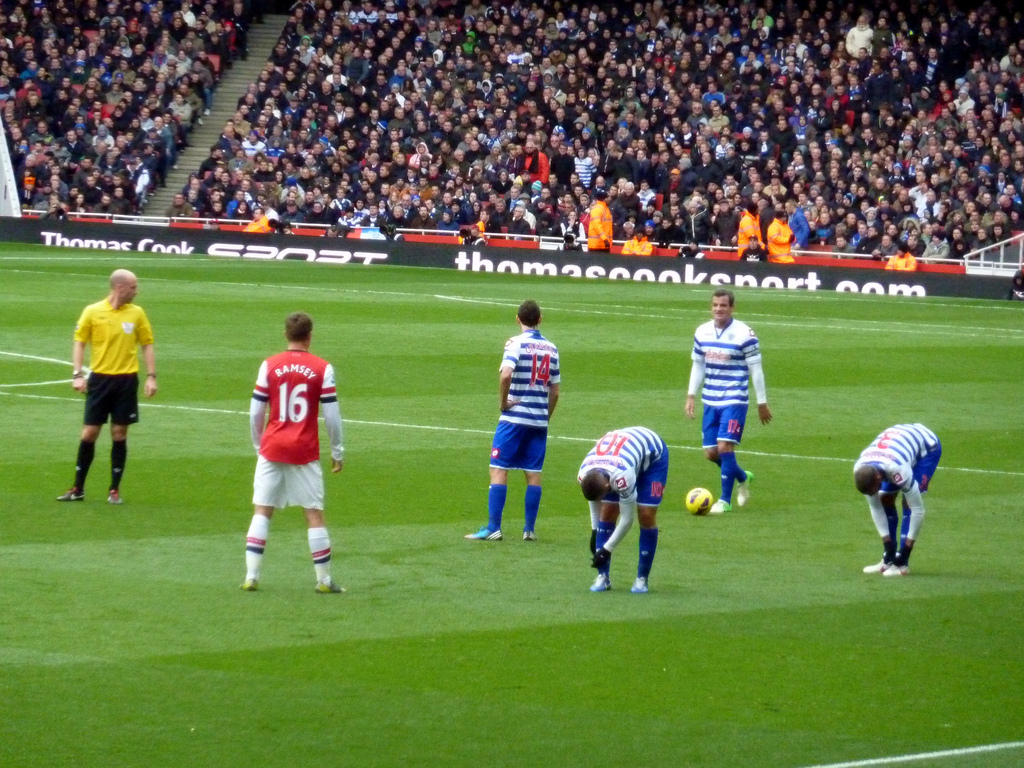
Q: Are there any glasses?
A: No, there are no glasses.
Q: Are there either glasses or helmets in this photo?
A: No, there are no glasses or helmets.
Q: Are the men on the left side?
A: Yes, the men are on the left of the image.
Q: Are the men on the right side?
A: No, the men are on the left of the image.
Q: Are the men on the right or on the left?
A: The men are on the left of the image.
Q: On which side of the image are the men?
A: The men are on the left of the image.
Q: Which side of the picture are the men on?
A: The men are on the left of the image.